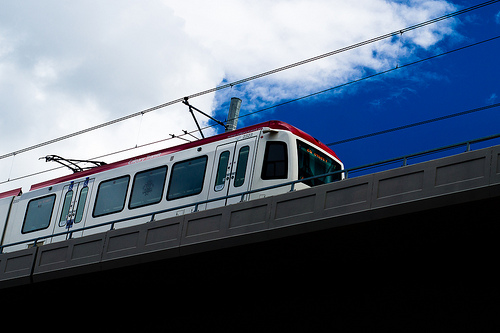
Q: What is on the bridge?
A: Bus.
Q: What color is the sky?
A: White and blue.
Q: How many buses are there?
A: One.